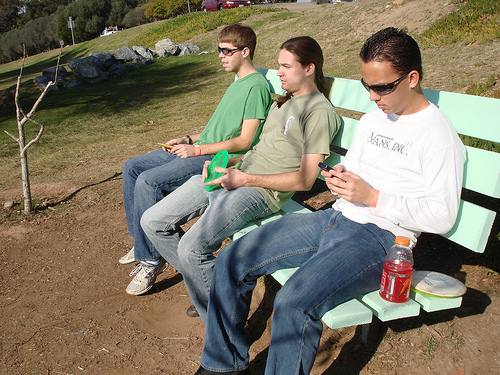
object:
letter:
[399, 146, 404, 154]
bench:
[233, 68, 498, 329]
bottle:
[379, 236, 414, 303]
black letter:
[393, 144, 403, 152]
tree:
[0, 42, 64, 215]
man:
[193, 26, 472, 375]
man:
[138, 36, 345, 327]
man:
[118, 26, 272, 297]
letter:
[369, 132, 379, 143]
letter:
[372, 138, 378, 147]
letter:
[377, 138, 385, 147]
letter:
[383, 140, 391, 150]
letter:
[391, 143, 398, 150]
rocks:
[153, 36, 182, 57]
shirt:
[329, 103, 468, 251]